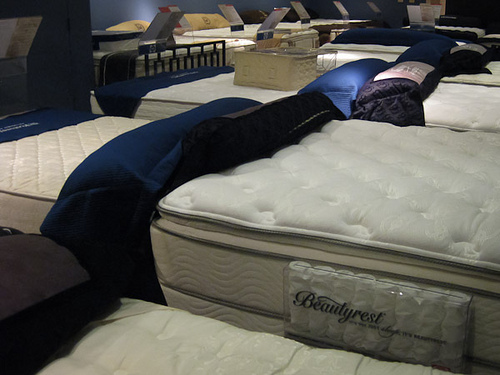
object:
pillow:
[40, 97, 265, 298]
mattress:
[0, 105, 157, 236]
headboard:
[144, 40, 227, 78]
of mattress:
[93, 48, 224, 91]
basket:
[230, 44, 318, 92]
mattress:
[90, 66, 356, 121]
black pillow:
[350, 59, 444, 128]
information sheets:
[138, 10, 186, 55]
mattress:
[150, 117, 499, 373]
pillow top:
[155, 119, 500, 285]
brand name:
[293, 289, 450, 350]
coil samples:
[285, 259, 474, 372]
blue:
[297, 57, 395, 120]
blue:
[331, 28, 459, 46]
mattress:
[318, 42, 462, 54]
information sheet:
[256, 7, 291, 41]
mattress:
[173, 35, 258, 68]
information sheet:
[217, 4, 245, 33]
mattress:
[182, 24, 320, 48]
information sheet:
[406, 4, 435, 32]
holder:
[409, 24, 436, 33]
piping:
[150, 216, 500, 300]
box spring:
[156, 279, 500, 374]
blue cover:
[95, 66, 236, 118]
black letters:
[359, 311, 371, 324]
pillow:
[157, 90, 349, 203]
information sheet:
[1, 16, 46, 117]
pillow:
[439, 42, 495, 78]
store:
[0, 0, 499, 375]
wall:
[90, 0, 500, 37]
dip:
[258, 206, 280, 226]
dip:
[345, 221, 373, 242]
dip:
[451, 238, 482, 259]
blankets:
[0, 106, 109, 144]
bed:
[0, 96, 266, 237]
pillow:
[182, 12, 232, 31]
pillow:
[105, 19, 153, 33]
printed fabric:
[373, 61, 435, 85]